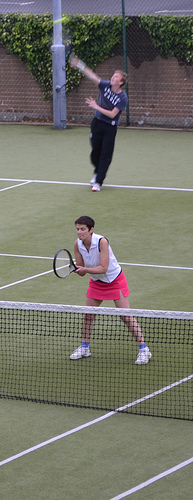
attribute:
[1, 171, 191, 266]
lines — white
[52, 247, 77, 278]
tennis racket — black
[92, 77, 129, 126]
t-shirt — blue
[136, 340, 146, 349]
sock — blue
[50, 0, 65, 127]
pole — gray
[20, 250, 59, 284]
lines — white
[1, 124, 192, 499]
court — tennis, green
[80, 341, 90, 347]
sock — blue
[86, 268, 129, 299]
skirt — hot pink, tennis, pink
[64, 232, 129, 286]
top — white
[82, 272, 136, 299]
skirt — red, mini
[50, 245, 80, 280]
racket — black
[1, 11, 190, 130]
wall — brick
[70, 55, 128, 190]
man —  standing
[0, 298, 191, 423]
mesh — tennis 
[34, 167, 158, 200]
lines — white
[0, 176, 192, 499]
lines — white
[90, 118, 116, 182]
pants — black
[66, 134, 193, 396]
court — tennis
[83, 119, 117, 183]
pants — black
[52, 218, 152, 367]
shirt — white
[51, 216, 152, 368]
player — lady, tennis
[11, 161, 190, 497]
court — tennis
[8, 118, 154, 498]
court — tennis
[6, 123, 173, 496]
court — tennis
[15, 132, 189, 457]
court — tennis, green